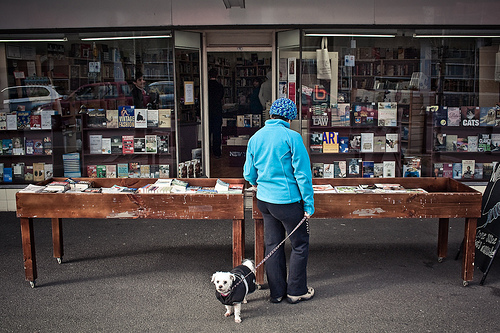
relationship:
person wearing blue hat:
[242, 97, 317, 307] [266, 95, 301, 119]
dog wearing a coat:
[191, 255, 278, 324] [229, 267, 262, 309]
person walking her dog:
[242, 97, 316, 304] [206, 261, 263, 319]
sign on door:
[181, 77, 198, 109] [174, 36, 209, 182]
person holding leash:
[242, 97, 316, 304] [226, 212, 303, 293]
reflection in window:
[39, 68, 166, 119] [4, 36, 201, 196]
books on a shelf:
[306, 99, 496, 178] [301, 115, 496, 178]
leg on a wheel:
[17, 218, 38, 280] [27, 281, 37, 289]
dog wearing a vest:
[210, 259, 255, 323] [214, 262, 256, 308]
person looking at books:
[242, 97, 316, 304] [215, 180, 227, 191]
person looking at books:
[242, 97, 316, 304] [228, 182, 243, 193]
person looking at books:
[242, 97, 316, 304] [365, 182, 409, 192]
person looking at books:
[242, 97, 316, 304] [45, 182, 68, 189]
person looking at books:
[242, 97, 316, 304] [333, 185, 365, 192]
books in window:
[309, 81, 427, 177] [276, 25, 465, 176]